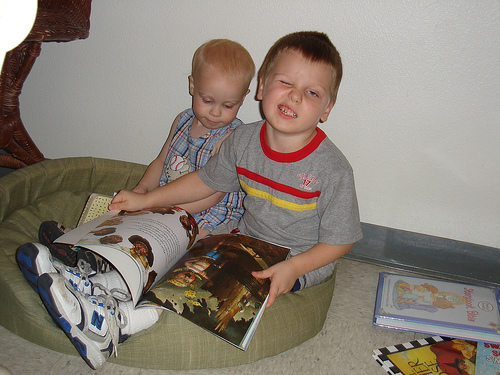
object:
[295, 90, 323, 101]
eye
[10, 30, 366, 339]
boy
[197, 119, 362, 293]
shirt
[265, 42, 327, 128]
face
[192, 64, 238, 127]
face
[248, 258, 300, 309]
hand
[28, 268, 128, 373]
sneakers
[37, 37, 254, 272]
boys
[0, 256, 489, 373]
floor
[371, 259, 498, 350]
children's book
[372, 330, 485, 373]
children's book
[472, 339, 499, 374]
children's book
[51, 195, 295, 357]
children's book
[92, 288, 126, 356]
white shoelaces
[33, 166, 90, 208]
pouf